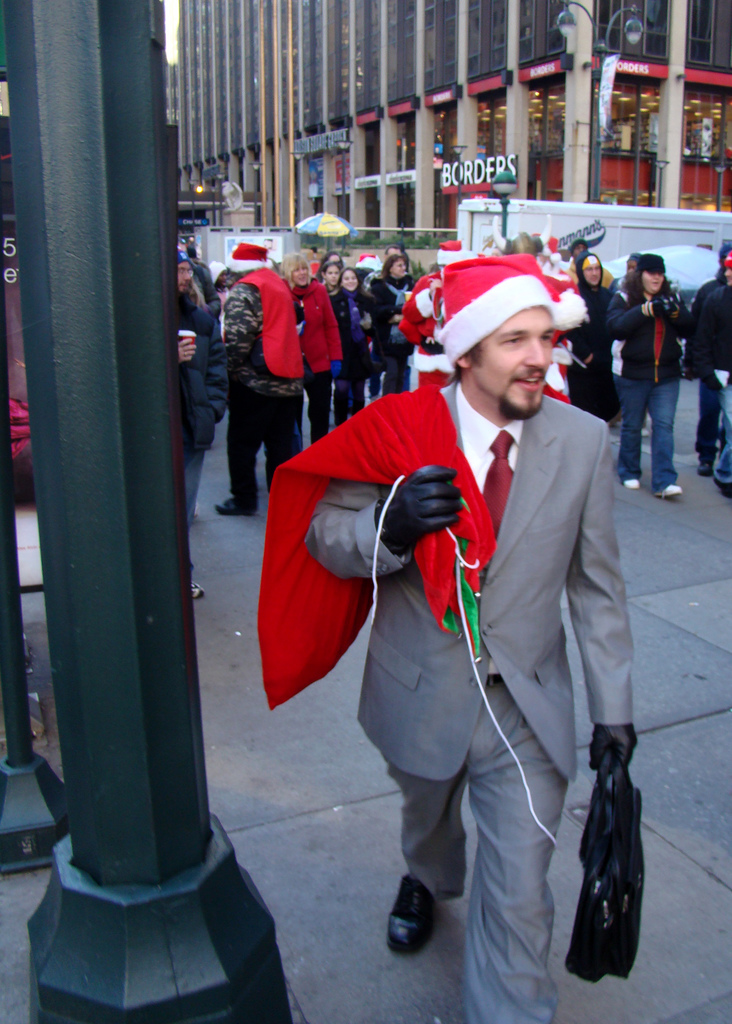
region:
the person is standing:
[632, 284, 674, 494]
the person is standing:
[415, 368, 563, 969]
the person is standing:
[218, 244, 290, 509]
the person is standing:
[329, 254, 384, 399]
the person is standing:
[159, 246, 215, 455]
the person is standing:
[571, 251, 618, 408]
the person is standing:
[363, 252, 406, 335]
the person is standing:
[289, 253, 339, 433]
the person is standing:
[685, 260, 716, 393]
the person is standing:
[364, 225, 408, 285]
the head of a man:
[434, 257, 551, 434]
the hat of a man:
[428, 255, 531, 345]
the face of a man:
[495, 306, 551, 406]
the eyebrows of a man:
[509, 316, 553, 337]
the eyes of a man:
[500, 328, 562, 351]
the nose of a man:
[513, 335, 549, 374]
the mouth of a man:
[517, 374, 545, 387]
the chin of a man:
[501, 389, 548, 410]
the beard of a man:
[498, 396, 545, 424]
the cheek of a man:
[475, 353, 523, 380]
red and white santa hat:
[416, 240, 596, 373]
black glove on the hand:
[581, 720, 638, 772]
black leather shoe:
[378, 869, 443, 950]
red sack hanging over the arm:
[256, 382, 516, 713]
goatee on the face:
[500, 361, 544, 422]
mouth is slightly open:
[512, 372, 558, 388]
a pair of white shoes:
[618, 469, 687, 503]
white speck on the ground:
[223, 620, 250, 641]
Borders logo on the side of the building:
[436, 150, 519, 196]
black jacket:
[610, 282, 693, 379]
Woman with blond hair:
[282, 251, 342, 458]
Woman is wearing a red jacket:
[280, 250, 338, 452]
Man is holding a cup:
[175, 248, 226, 599]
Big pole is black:
[1, 2, 293, 1022]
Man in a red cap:
[229, 267, 303, 384]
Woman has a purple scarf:
[344, 279, 370, 345]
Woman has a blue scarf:
[383, 278, 415, 344]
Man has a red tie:
[478, 427, 515, 540]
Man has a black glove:
[378, 459, 462, 556]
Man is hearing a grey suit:
[306, 255, 631, 1022]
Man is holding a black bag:
[565, 750, 644, 982]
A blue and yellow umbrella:
[295, 210, 358, 253]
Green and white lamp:
[490, 171, 517, 243]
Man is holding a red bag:
[257, 383, 495, 709]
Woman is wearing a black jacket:
[605, 252, 688, 498]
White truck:
[456, 197, 729, 266]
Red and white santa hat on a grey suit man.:
[436, 255, 585, 364]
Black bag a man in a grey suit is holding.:
[566, 750, 645, 984]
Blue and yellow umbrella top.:
[293, 212, 356, 238]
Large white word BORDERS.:
[440, 155, 517, 188]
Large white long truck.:
[456, 197, 729, 275]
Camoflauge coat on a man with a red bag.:
[219, 280, 304, 399]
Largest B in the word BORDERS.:
[441, 161, 451, 188]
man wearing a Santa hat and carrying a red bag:
[256, 251, 643, 1021]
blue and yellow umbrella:
[293, 210, 359, 241]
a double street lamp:
[551, 2, 645, 201]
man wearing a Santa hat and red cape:
[212, 243, 302, 514]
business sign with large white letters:
[441, 154, 519, 185]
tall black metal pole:
[3, 0, 290, 1021]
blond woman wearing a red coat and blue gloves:
[279, 254, 343, 458]